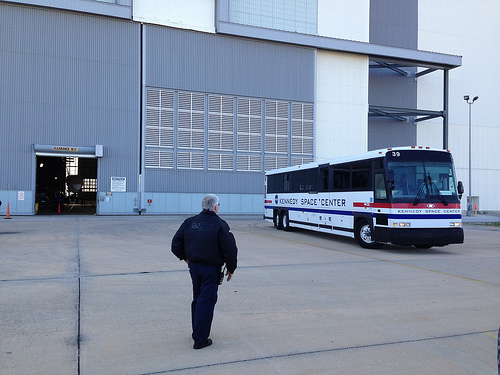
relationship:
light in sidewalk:
[462, 93, 479, 218] [461, 212, 499, 227]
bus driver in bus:
[167, 190, 242, 352] [262, 141, 467, 255]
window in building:
[144, 87, 176, 170] [0, 3, 448, 229]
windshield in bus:
[382, 157, 458, 199] [262, 144, 467, 243]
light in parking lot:
[462, 93, 479, 218] [2, 59, 497, 370]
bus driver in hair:
[170, 194, 239, 351] [198, 195, 218, 212]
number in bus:
[388, 146, 408, 161] [262, 141, 467, 255]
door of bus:
[368, 161, 392, 230] [262, 141, 467, 255]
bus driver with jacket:
[170, 194, 239, 351] [167, 209, 241, 276]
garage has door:
[23, 142, 116, 240] [32, 147, 102, 217]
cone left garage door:
[4, 201, 12, 220] [34, 144, 104, 217]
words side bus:
[278, 199, 343, 206] [262, 141, 467, 255]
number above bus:
[392, 151, 401, 158] [262, 141, 467, 255]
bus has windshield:
[245, 137, 465, 246] [386, 155, 456, 193]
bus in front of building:
[262, 141, 467, 255] [22, 7, 470, 206]